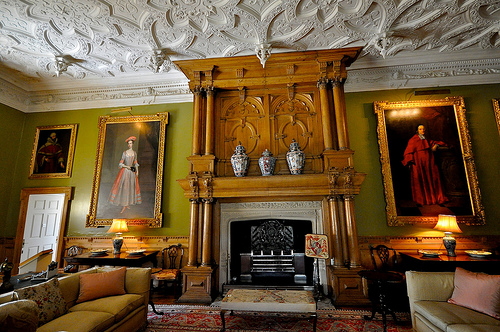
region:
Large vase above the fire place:
[225, 133, 252, 178]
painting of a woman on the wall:
[92, 105, 165, 230]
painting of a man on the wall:
[366, 92, 490, 227]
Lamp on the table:
[431, 208, 463, 256]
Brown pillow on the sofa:
[66, 257, 138, 299]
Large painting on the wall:
[93, 111, 162, 231]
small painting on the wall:
[21, 122, 79, 180]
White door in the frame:
[21, 192, 58, 272]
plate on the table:
[126, 243, 148, 256]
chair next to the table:
[148, 235, 180, 297]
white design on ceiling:
[0, 21, 55, 74]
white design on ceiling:
[44, 27, 84, 56]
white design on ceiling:
[99, 21, 149, 55]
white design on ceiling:
[152, 7, 194, 54]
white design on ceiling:
[224, 18, 273, 61]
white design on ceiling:
[267, 5, 329, 55]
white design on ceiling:
[348, 2, 398, 42]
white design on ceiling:
[419, 8, 470, 60]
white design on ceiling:
[280, 6, 328, 24]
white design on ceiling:
[368, 35, 400, 65]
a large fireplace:
[212, 200, 327, 287]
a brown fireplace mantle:
[169, 168, 366, 196]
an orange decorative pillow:
[74, 266, 131, 296]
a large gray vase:
[230, 140, 250, 176]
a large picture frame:
[89, 115, 174, 231]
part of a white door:
[15, 190, 68, 265]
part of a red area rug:
[150, 288, 397, 330]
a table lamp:
[107, 217, 129, 256]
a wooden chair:
[146, 243, 187, 293]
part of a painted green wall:
[164, 140, 197, 177]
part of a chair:
[468, 261, 474, 274]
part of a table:
[288, 302, 301, 305]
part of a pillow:
[118, 287, 137, 309]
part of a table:
[280, 286, 295, 311]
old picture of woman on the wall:
[97, 107, 167, 242]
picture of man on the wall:
[368, 99, 480, 219]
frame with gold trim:
[373, 81, 485, 233]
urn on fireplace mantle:
[228, 143, 245, 179]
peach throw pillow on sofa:
[75, 257, 127, 297]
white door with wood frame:
[15, 182, 75, 266]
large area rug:
[144, 300, 396, 330]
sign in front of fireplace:
[305, 227, 330, 267]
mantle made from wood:
[181, 50, 357, 190]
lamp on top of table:
[427, 210, 464, 252]